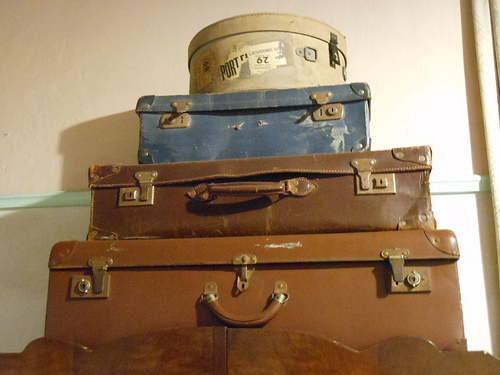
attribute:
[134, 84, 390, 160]
suitcase — blue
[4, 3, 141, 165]
wall — white, house wall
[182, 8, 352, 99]
box — round, metallic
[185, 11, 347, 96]
box — leather, hat box, white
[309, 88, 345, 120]
latch — metal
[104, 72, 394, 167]
suitcase — blue, stacked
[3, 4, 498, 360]
wall — clean, house wall, white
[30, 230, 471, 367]
cupboard — brown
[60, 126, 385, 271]
suitcase — stacked, brown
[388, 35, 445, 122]
wall — house wall, white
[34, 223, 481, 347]
box — metallic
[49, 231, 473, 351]
box — brown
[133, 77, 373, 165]
box — blue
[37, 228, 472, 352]
suitcase — tan, stacked, brown, leather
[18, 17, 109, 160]
wall — white, house wall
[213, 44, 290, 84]
sticker — white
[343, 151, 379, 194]
latch — metal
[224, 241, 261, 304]
latch — metal